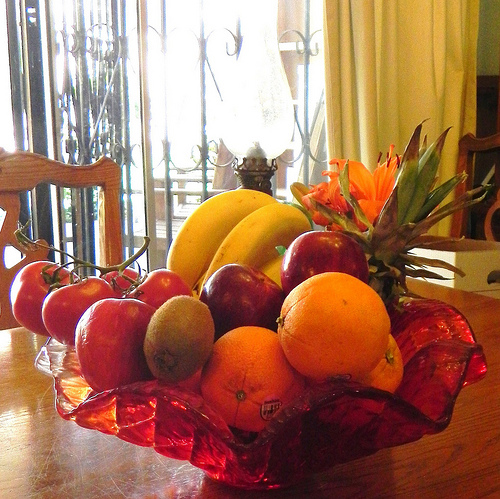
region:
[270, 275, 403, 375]
a round orange in bowl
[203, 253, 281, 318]
a red apple in bowl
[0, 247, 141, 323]
a bunch of tomatoes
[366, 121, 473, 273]
the top of a pineapple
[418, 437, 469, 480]
TABLE MADE OF WOOD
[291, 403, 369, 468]
GLASS DISH SITTING ON THE TABLE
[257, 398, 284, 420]
STICKER ON THE FRUIT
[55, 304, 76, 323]
TOMATOE IN THE BOWL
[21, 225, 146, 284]
VINE HOLDING THE TOMATOES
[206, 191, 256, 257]
BANANAS IN THE BOWL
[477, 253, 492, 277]
WHITE BOX TOP ON THE TABLE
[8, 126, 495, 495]
Fruit and vegetables in a bowl.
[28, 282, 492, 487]
A red glass serving dish.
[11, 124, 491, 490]
Fruit and vegetables in a glass dish.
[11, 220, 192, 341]
Tomatoes on the vine.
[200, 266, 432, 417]
Oranges are in the dish.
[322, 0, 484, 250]
White curtains on the window.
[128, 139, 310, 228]
A bench is seen outside the window.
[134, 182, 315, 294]
Yellow bananas in the bowl.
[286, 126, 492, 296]
A plant with orange flowers on the table.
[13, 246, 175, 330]
red tomatoes on a vine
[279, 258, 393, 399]
a orange in a red bowl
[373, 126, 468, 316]
a pineapple in a red bowl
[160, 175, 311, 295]
yellow bananas in a bowl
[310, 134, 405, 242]
a orange flower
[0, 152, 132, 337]
a wood chair next to a table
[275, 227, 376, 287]
a red apple in a bowl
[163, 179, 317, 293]
yellow ripe bananas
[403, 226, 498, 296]
a white card board box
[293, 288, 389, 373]
an orange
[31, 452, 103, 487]
the table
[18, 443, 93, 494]
the table is brown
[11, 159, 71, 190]
the chair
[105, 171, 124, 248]
the chair is brown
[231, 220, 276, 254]
the banana peel is yellow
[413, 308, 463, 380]
a red bowl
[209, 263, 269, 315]
the apple is red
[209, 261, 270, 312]
a red apple in the bowl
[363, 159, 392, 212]
the flowers are orange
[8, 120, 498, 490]
Fruit and vegetables in a bowl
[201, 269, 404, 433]
Three oranges in the bowl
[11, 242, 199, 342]
Red toatoes on the vine in the bowl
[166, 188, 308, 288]
Yellow bananas in the bowl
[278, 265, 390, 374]
orange is in the bowl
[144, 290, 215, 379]
kiwi is in the bowl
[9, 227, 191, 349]
tomatoes are in the bowl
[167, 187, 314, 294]
bananas are in the bowl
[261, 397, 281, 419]
sticker is on the orange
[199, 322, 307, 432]
orange is in the bowl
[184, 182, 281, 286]
banana that is in a bowl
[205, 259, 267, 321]
a red apple that is in a bowl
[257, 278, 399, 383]
an orange that is in a bowl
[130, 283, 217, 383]
a kiwi that is in a bowl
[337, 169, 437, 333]
a pineapple that is in a bowl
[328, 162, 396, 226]
a flower that is in a bowl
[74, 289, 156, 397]
a fuji apple that is in a bowl